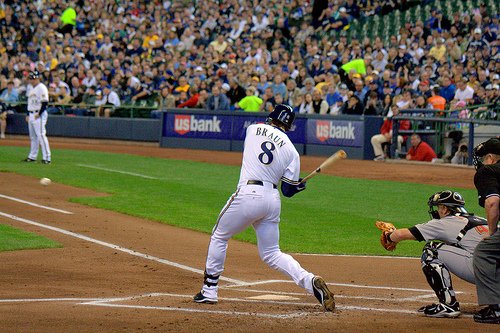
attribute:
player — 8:
[194, 103, 334, 311]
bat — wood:
[298, 151, 346, 187]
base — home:
[248, 287, 302, 303]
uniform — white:
[28, 86, 50, 161]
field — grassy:
[1, 135, 499, 326]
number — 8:
[257, 141, 274, 167]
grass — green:
[3, 145, 500, 254]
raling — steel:
[394, 109, 499, 164]